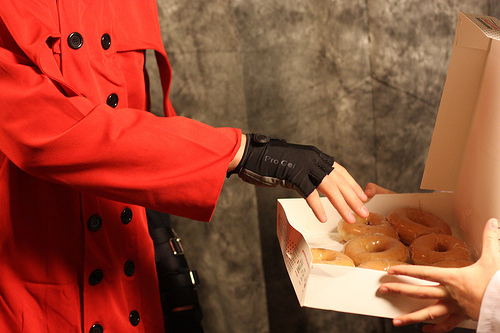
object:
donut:
[342, 229, 412, 264]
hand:
[373, 218, 499, 330]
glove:
[226, 133, 335, 199]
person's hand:
[234, 132, 369, 225]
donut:
[335, 213, 395, 243]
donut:
[385, 207, 452, 246]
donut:
[409, 232, 469, 267]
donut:
[309, 249, 355, 269]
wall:
[162, 0, 471, 180]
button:
[113, 203, 132, 226]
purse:
[142, 207, 206, 332]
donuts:
[336, 211, 396, 243]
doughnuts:
[352, 258, 418, 275]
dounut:
[342, 233, 409, 262]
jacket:
[0, 0, 242, 333]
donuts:
[428, 260, 474, 270]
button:
[96, 26, 118, 52]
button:
[67, 27, 86, 52]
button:
[114, 204, 136, 224]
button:
[81, 212, 113, 232]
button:
[84, 262, 106, 291]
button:
[62, 26, 86, 52]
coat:
[3, 2, 242, 332]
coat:
[22, 10, 262, 331]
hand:
[217, 100, 365, 238]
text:
[261, 155, 296, 170]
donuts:
[406, 233, 471, 262]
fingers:
[383, 264, 469, 286]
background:
[235, 50, 318, 132]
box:
[57, 7, 158, 330]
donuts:
[384, 205, 451, 244]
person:
[0, 0, 370, 333]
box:
[274, 10, 484, 314]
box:
[256, 216, 358, 306]